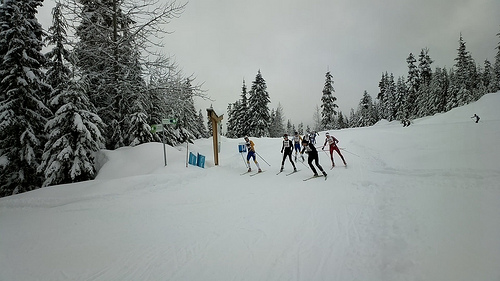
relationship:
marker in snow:
[206, 103, 224, 165] [171, 170, 189, 182]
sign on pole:
[152, 116, 174, 133] [161, 123, 168, 170]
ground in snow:
[202, 116, 356, 186] [25, 92, 499, 279]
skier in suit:
[241, 134, 263, 176] [243, 139, 259, 168]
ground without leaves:
[336, 85, 368, 126] [62, 156, 69, 167]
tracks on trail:
[354, 134, 415, 274] [297, 143, 432, 278]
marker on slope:
[188, 95, 253, 151] [250, 139, 375, 277]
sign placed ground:
[151, 118, 177, 166] [241, 190, 366, 273]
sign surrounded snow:
[151, 118, 177, 166] [153, 181, 260, 251]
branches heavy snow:
[78, 111, 105, 146] [10, 105, 492, 274]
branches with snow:
[78, 111, 105, 146] [10, 105, 492, 274]